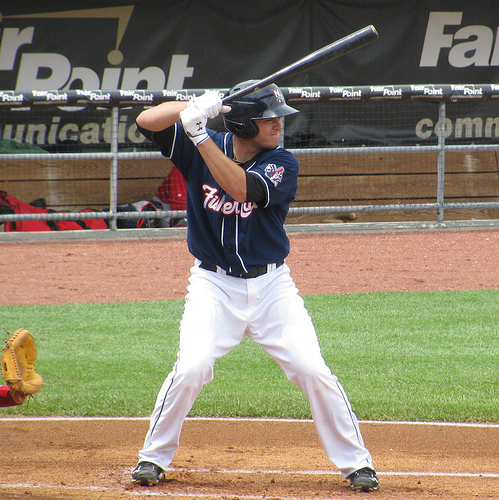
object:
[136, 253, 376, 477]
pants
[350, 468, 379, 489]
shoes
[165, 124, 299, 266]
jersey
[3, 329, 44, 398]
mitt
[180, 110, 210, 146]
gloves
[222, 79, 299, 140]
helmet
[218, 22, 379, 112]
bat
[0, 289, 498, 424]
area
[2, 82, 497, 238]
fence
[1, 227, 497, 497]
field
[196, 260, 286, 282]
belt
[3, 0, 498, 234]
dugout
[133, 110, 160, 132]
elbow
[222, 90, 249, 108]
handle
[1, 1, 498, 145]
sign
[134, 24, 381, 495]
man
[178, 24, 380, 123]
baseball